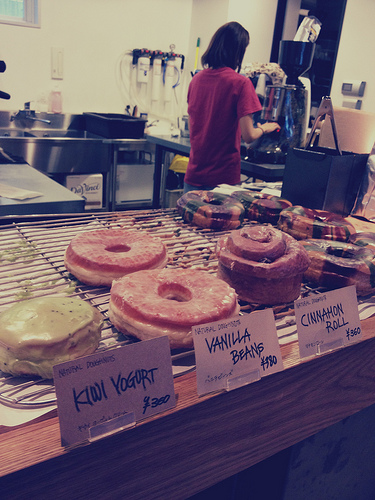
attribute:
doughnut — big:
[113, 262, 270, 358]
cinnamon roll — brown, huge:
[216, 217, 309, 312]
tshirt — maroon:
[181, 62, 255, 181]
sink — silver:
[25, 122, 120, 180]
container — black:
[284, 141, 369, 235]